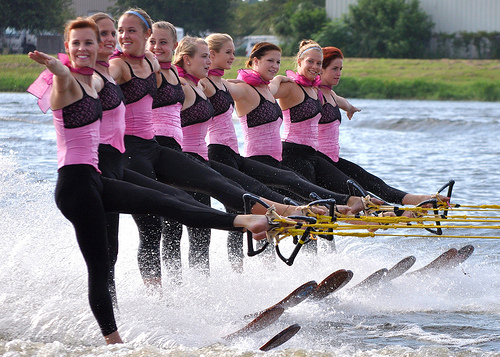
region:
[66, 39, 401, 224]
ladies are in water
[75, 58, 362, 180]
ladies are dressed in same outfit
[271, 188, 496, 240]
the ladies are holding sticks with their hands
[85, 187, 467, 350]
both the ladies are on surfboards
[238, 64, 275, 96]
neck scarfs are pink in color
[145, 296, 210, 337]
part of the water waves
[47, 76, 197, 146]
the blouses are pink and white in coor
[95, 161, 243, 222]
pants are black in color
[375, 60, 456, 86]
grasses are green in color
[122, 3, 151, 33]
head scarf is blue in color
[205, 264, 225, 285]
part of a splash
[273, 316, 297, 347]
edge of a board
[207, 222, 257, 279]
part of a splash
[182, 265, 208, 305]
part of a splash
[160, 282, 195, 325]
part of a water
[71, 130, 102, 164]
a pink tank top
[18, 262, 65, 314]
a splash of water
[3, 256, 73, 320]
the water is white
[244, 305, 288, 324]
a ski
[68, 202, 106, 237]
women is wearing black leggings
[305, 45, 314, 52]
a headband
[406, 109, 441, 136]
a small wave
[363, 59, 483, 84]
a field of green grass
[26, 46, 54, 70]
the womens hand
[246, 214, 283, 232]
the womens foot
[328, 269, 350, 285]
edge of a line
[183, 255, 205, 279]
part of a splash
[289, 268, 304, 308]
part of a board